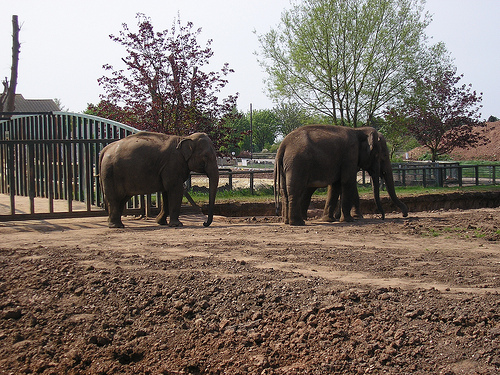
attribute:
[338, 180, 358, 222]
leg — elephant's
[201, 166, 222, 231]
trunk — elephant's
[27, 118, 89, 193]
fence — metal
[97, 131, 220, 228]
elephant — in the picture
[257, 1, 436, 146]
leaves — green 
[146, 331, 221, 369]
soil — black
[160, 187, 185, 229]
legs — in the picture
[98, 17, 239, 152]
tree — purple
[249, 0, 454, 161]
tree — Part , purple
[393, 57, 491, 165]
tree — purple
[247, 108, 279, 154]
tree — purple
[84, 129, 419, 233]
elephants — in the picture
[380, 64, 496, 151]
leaves — red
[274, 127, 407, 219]
elephant — in the picture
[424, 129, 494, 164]
soil — brown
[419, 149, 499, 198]
fence — part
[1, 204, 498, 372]
dirt — loose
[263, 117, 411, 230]
elephant — brown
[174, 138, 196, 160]
ear — elephant's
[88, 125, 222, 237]
elephant — brown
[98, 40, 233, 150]
tree — part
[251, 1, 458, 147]
leaves — green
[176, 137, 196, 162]
ear — in the picture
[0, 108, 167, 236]
gate — metal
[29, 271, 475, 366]
dirt — part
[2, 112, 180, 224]
metal fencing — metal 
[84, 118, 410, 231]
elephants — in the picture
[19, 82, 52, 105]
roof — metal, brown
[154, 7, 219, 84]
leaves — red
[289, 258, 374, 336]
floor — dirt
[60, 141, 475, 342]
enclosure — elephant